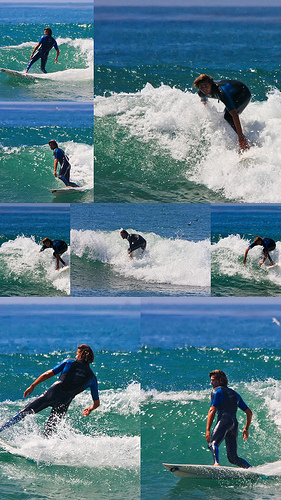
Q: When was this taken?
A: Daytime.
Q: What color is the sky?
A: Blue.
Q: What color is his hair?
A: Blonde.